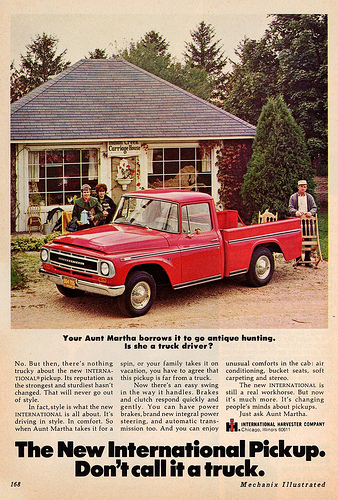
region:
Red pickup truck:
[38, 164, 315, 311]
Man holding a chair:
[284, 175, 328, 265]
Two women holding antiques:
[62, 182, 126, 243]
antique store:
[15, 47, 253, 236]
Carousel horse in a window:
[142, 155, 209, 200]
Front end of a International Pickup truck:
[32, 239, 122, 298]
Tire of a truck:
[114, 257, 169, 322]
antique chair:
[20, 195, 53, 240]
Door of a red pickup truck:
[168, 223, 237, 293]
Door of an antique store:
[102, 127, 152, 230]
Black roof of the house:
[74, 75, 117, 123]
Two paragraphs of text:
[12, 359, 116, 431]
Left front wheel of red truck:
[122, 267, 157, 311]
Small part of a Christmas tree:
[269, 109, 289, 126]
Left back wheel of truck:
[252, 251, 276, 285]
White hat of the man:
[295, 179, 308, 184]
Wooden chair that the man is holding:
[304, 218, 318, 260]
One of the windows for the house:
[28, 150, 74, 202]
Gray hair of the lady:
[82, 184, 89, 189]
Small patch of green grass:
[319, 231, 326, 237]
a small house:
[28, 56, 259, 223]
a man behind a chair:
[281, 179, 319, 251]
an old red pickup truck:
[58, 198, 311, 288]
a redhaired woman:
[94, 184, 122, 209]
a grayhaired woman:
[75, 185, 94, 224]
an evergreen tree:
[251, 106, 313, 213]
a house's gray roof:
[34, 70, 245, 142]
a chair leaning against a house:
[23, 198, 44, 237]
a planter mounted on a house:
[112, 160, 130, 189]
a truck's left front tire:
[119, 268, 155, 319]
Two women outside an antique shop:
[76, 180, 114, 222]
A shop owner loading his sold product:
[283, 176, 323, 270]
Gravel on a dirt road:
[244, 292, 320, 318]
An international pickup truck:
[36, 193, 301, 323]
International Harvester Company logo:
[224, 416, 330, 436]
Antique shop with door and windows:
[13, 62, 254, 229]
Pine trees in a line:
[280, 19, 323, 173]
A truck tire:
[241, 240, 283, 287]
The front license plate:
[57, 271, 84, 295]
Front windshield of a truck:
[116, 195, 185, 234]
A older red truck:
[30, 186, 312, 321]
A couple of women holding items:
[48, 177, 133, 235]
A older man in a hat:
[284, 176, 321, 218]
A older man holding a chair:
[280, 180, 337, 272]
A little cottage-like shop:
[1, 24, 258, 243]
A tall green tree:
[240, 85, 321, 225]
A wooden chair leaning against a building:
[17, 195, 50, 233]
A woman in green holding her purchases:
[63, 177, 103, 228]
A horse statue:
[146, 159, 221, 197]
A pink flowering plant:
[117, 163, 135, 182]